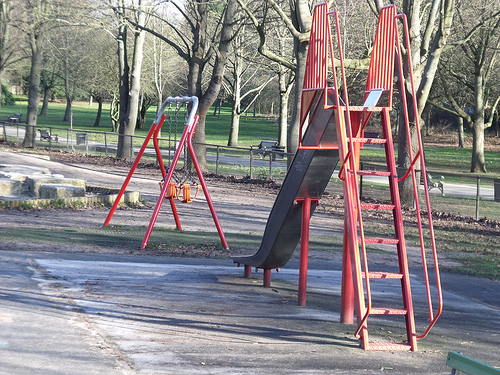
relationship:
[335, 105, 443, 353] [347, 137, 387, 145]
ladder has rung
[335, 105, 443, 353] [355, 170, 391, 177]
ladder has rung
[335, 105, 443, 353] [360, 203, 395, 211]
ladder has rung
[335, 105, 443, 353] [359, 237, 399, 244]
ladder has rung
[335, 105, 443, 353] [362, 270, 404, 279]
ladder has rung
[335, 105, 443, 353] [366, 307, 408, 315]
ladder has rung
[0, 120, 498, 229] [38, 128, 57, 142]
fence behind bench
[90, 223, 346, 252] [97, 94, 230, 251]
astro turf under swing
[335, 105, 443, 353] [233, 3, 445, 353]
ladder on slide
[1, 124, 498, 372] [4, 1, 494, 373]
playground i at park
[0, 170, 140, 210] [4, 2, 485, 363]
structure on playground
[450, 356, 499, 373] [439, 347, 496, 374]
top on bench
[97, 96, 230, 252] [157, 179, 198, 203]
swing has seats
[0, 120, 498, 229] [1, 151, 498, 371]
fence surrounding park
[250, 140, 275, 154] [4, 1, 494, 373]
bench sitting in park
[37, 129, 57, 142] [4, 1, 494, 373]
bench sitting in park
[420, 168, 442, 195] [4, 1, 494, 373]
bench sitting in park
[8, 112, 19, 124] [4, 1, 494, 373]
bench sitting in park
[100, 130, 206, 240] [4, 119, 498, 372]
path along public park